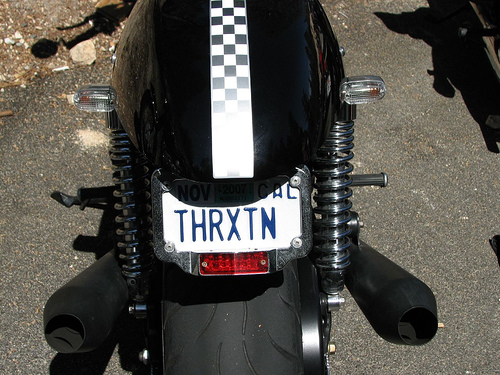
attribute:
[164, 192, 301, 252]
plate — white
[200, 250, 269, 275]
taillight — red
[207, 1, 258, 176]
line — long, checkered, black, white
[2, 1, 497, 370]
ground — paved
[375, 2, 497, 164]
shadow — cast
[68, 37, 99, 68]
rock — white, large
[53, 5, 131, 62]
handle bar — black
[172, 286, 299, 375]
tire — worn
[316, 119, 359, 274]
spring — silver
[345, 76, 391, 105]
light — small, blinker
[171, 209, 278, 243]
letters — blue, capital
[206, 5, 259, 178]
design — checkerboard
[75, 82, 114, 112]
signal — blinker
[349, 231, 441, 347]
muffler — black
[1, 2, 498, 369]
pavement — black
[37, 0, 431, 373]
bike — parked